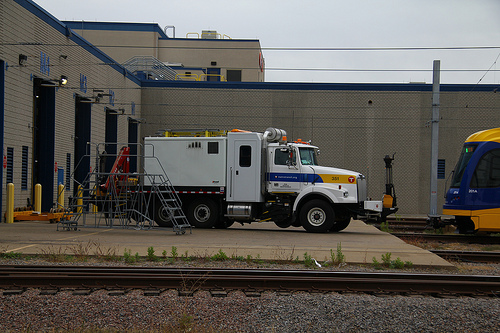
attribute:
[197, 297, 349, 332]
rocks — to keep vegetation from growing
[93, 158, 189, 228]
stair case — movable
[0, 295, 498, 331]
rocks — to facilitate water drainage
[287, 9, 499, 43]
sky — grey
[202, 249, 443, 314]
rails — for train to glide on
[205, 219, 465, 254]
road — paved, for easier transfer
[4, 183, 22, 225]
pole — yellow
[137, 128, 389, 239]
truck — white